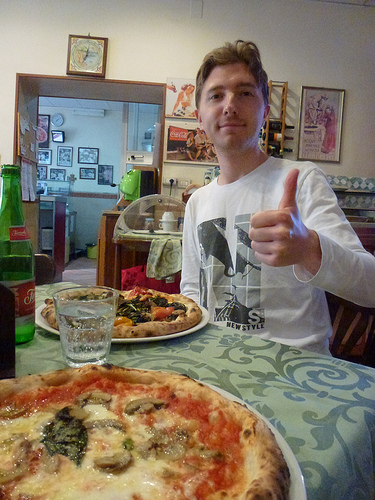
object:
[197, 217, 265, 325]
logo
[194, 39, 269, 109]
hair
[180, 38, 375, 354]
guy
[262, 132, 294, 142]
wine bottle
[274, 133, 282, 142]
label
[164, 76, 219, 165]
poster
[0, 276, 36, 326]
red labels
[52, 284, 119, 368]
cup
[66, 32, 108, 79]
picture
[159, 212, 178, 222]
cup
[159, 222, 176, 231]
cup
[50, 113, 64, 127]
clock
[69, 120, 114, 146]
wall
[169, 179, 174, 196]
cord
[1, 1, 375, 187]
wall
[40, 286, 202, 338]
pizza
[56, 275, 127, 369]
glass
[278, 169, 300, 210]
thumb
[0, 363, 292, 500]
pizza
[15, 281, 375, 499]
table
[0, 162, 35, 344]
bottle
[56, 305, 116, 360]
liquid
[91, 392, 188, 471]
mushrooms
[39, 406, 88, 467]
spinach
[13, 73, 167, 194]
doorway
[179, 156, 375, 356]
shirt